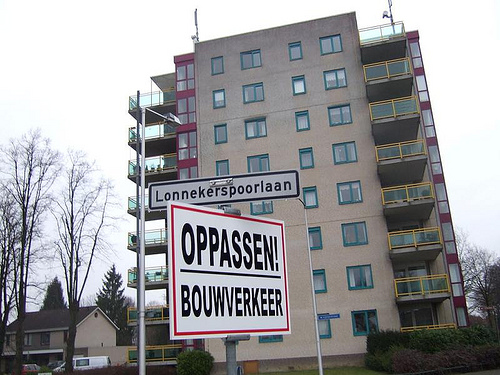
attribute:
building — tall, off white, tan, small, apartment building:
[128, 11, 470, 373]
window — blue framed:
[241, 48, 262, 69]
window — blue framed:
[243, 82, 265, 104]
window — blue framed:
[244, 116, 267, 139]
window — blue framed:
[297, 111, 310, 131]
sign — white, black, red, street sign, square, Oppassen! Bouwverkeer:
[166, 201, 290, 340]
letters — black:
[178, 222, 284, 316]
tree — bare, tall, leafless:
[39, 147, 129, 374]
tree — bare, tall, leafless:
[0, 125, 62, 374]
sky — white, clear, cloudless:
[0, 2, 500, 318]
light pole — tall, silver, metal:
[140, 105, 183, 373]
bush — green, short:
[366, 326, 499, 372]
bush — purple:
[385, 343, 500, 374]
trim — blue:
[292, 73, 308, 95]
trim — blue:
[295, 109, 313, 130]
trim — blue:
[298, 145, 316, 171]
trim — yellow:
[361, 55, 411, 80]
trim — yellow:
[369, 94, 422, 124]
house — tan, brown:
[1, 305, 120, 371]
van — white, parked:
[51, 355, 109, 374]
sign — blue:
[145, 168, 300, 210]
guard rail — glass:
[393, 273, 450, 299]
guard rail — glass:
[388, 226, 443, 251]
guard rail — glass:
[381, 181, 435, 207]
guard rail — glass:
[374, 137, 426, 160]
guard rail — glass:
[129, 344, 181, 362]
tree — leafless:
[453, 227, 498, 325]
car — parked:
[20, 362, 43, 374]